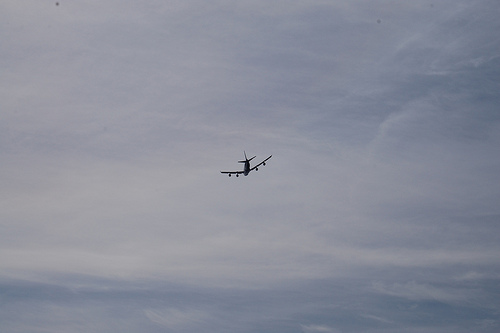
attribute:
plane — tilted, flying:
[218, 150, 274, 180]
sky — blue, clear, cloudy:
[0, 1, 499, 331]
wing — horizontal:
[252, 152, 272, 170]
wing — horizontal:
[221, 166, 243, 177]